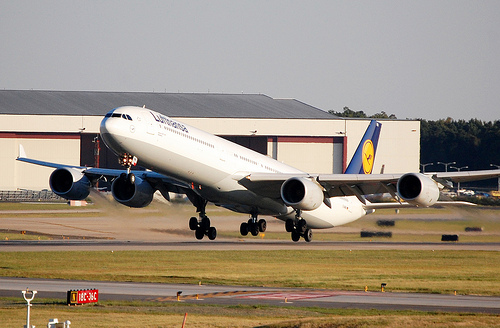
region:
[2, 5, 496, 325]
The picture is taken during the daytime.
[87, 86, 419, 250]
This is a Luftansia plane.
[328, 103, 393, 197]
The tail of the plane is blue and yellow.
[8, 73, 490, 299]
This plane is taking off of the runway.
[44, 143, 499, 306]
This plane has four engines.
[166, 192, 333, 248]
The landing gear of the plane is down.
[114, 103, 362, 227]
The body of the plane is white.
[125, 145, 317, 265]
Underneath the plane the pain is grey.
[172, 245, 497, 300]
The grass is cut very low.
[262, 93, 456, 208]
A plane hangar is seen behind the plane.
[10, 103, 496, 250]
an airplane taking off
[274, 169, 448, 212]
two engines on a airplane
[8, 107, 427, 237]
a airplane hanger and an airplane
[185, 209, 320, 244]
sixteen airplane wheels and tires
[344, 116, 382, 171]
a blue and yellow airplane tail.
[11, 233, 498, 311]
two airplane runways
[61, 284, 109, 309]
an airport runway sign.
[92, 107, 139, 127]
airplane windshield windows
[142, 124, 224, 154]
airplane passenger windows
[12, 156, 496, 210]
airplane wings with four engines.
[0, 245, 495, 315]
a runway for airplanes taking off and landing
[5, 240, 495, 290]
wilting grass next to runway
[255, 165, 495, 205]
wing of airplane with two engines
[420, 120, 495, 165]
green trees next to hangar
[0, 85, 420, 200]
airplane hangar for parking planes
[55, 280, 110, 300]
numbered runway sign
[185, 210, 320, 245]
landing gear is down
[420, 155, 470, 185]
streetlights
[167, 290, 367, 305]
runway markings for pilots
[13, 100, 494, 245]
A white airplane lifting off the runway.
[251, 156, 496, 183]
A white airplane wing.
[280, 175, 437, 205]
Two airplane engines under the wing.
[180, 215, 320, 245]
Twelve airplane tires lifting off the runway.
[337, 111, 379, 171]
Blue tail of the airplane with a gold circle.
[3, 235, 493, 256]
The runway under the plane.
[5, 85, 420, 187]
A white airplane hangar trimmed in red.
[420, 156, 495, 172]
Lights in the parking lot.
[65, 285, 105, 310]
A red sign near the runway.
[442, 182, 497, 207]
Cars in the parking lot.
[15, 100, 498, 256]
White airplane has blue and yellow tail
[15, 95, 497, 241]
Lufthansa airplane is white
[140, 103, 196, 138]
Lufthansa logo is blue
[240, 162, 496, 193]
Airplane wing is white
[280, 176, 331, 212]
Airplane engine is cylindrical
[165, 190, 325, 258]
Airplane landing gear is down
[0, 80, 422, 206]
Airplane hangar is white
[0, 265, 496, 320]
Airport runway is asphalt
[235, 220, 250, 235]
Airplane tire is round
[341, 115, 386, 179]
Blue and yellow airplane tail